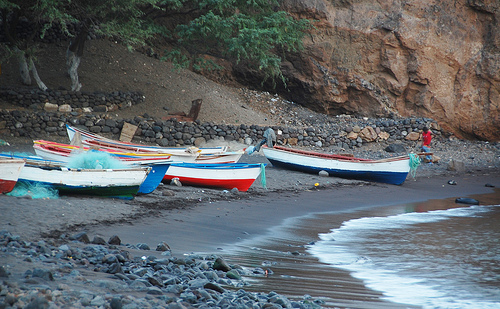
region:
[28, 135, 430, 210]
boats sitting on sand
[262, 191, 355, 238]
wet edge of shore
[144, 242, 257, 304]
rocks in beach sand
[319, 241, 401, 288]
white foam on water's edge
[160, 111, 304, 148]
stone wall behind boats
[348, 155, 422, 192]
white and blue boat on shore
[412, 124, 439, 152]
person in red shirt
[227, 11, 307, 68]
green leaves on tree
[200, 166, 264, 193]
front of red and white boat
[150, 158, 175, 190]
front of blue boat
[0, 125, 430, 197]
row of colorful boats sitting on shore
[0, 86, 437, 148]
row of pebbles laying on shore behind boats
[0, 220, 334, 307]
stack of pebbles sitting on shore in front of boats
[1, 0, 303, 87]
small trees behind row of pebbles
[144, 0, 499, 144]
huge rock cliff in background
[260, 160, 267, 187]
fabric hanging from boat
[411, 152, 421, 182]
string hanging from boat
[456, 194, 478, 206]
black rock laying on shore near water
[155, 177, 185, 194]
pebbles laying in middle of two boats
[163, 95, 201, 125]
rusty,metal item behind pebbles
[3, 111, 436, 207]
Boats are standing in ground.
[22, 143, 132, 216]
Net is blue color.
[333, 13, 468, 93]
Rock is brown color.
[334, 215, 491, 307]
Water is brown color.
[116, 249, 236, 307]
Small rocks are grey color.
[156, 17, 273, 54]
Trees are green color.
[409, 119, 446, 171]
Man is walking in sand.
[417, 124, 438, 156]
Man is wearing red shirt.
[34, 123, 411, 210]
Boats are white, red and blue color.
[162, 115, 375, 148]
Rocks are behind the boat.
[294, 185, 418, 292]
the water is white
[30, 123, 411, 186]
the boats are on the shore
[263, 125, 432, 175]
the boat is made of wood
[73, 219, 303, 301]
the rocks are wet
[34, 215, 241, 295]
the rocks are grey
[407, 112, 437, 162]
a person is walking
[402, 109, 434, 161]
a person is wearing a red shirt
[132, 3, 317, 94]
he leaves are very healthy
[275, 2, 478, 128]
the rock is brown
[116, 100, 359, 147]
a wall of rock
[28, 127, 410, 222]
numerous boats on shore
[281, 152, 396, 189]
white boat on shore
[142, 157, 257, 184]
red, white, and blue boat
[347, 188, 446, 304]
water washing up on shore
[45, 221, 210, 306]
grey rocks near water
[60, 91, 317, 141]
grey rocks form wall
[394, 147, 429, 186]
person standing near boat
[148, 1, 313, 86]
green trees on hill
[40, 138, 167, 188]
dark blue boat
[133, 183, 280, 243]
dark grey sand on beach